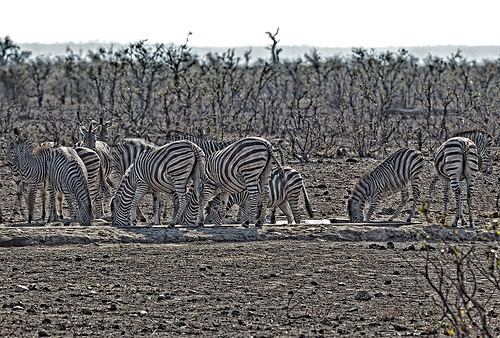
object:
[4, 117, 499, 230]
group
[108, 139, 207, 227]
zebras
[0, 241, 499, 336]
soil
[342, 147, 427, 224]
zebra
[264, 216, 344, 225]
water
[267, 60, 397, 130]
section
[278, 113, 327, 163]
shrubbery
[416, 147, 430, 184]
tail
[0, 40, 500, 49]
skyline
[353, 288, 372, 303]
rock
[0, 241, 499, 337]
ground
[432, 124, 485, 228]
zebra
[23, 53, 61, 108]
trees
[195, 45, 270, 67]
hills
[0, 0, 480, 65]
background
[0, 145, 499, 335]
dirt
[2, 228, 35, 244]
rocks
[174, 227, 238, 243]
stones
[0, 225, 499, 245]
enclosure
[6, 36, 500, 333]
environment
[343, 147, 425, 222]
side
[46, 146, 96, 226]
zebras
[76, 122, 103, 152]
heads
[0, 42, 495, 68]
mountains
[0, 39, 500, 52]
horizon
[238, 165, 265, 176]
stripes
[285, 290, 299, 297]
rocks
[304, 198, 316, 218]
hair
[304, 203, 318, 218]
tip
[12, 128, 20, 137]
fur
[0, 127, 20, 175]
head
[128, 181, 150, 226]
legs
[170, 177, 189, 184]
stripes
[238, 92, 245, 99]
leaves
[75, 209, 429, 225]
hole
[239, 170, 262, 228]
legs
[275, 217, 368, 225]
edge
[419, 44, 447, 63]
row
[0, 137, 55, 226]
zebra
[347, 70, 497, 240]
right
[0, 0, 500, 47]
sky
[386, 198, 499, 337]
vegetation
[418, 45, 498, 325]
right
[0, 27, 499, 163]
vegetation